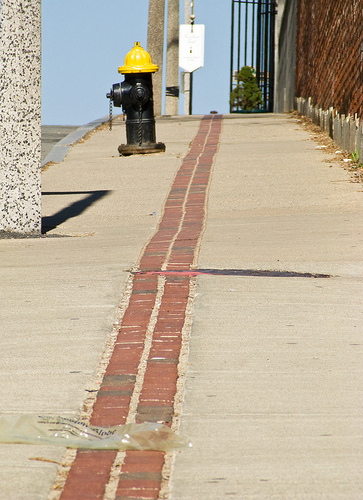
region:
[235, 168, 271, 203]
part of a floor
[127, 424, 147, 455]
part of a paper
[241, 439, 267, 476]
par tof a floor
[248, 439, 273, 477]
part of a floor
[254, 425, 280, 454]
part of a floor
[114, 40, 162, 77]
Yellow top on a black hydrant.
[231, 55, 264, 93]
Yellow top on a black hydrant.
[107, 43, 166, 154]
Black and yellow fire hydrant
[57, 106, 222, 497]
The brick is red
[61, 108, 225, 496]
Two rows of brick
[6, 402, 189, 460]
Plastic bag on side walk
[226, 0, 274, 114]
the fence is black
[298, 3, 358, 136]
The wall is brick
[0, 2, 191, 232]
The poles are grey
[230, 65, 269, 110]
Green bush in front of fence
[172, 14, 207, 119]
White sign with black pole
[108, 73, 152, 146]
black chains on the fire hydrant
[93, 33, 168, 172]
black and yellow hydrant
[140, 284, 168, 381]
red brick lines on sidewalk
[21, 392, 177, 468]
plastic bag on sidewalk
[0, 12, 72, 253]
stone pillar on left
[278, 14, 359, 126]
brick wall on right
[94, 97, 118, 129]
chain hanging from hydrant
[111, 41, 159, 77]
yellow top of hydrant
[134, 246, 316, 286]
man hole cover on sidewalk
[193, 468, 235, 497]
old gum on sidewalk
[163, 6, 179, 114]
wood poles at end of sidewalk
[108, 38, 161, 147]
this is a hydrant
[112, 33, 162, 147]
the hydrant is metallic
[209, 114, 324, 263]
this is the pavemet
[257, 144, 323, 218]
the pavement is clean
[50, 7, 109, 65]
this is the sky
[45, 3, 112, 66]
the sky is clear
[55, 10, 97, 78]
the sky is blue in color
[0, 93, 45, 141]
this is a pillar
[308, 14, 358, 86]
this is the wall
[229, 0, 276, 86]
this is a gate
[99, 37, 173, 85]
The top of the hydrant is yellow